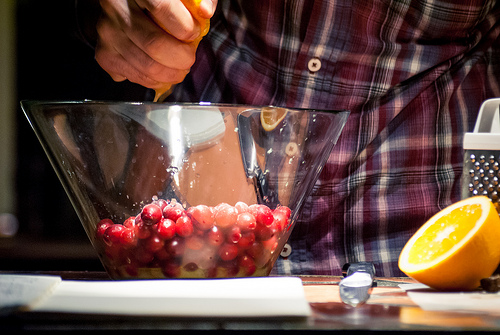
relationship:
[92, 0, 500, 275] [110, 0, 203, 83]
man squeezing orange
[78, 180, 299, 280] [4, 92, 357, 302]
grapes in bowl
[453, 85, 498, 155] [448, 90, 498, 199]
handle on grater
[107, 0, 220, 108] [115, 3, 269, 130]
hand squeezing fruit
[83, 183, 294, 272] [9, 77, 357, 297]
berries in bowl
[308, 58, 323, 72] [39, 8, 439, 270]
button on shirt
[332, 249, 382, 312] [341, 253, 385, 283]
knife has handle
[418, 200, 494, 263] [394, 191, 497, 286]
skin on exterior of fruit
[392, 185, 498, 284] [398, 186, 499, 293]
half of an orange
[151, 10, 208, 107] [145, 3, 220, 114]
cut half of an orange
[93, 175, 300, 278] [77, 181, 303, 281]
bunch of cherries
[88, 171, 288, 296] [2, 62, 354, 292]
cherries inside bowl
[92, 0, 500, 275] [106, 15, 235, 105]
man squeezing an orange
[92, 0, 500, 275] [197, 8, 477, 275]
man wearing shirt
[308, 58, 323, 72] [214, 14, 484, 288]
button on shirt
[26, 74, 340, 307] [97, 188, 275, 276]
bowl of berries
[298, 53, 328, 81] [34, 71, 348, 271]
button above a bowl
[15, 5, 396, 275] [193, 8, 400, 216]
man in shirt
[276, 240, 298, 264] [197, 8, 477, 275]
button on a shirt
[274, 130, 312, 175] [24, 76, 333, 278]
button through a bowl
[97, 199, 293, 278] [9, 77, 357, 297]
berries inside a bowl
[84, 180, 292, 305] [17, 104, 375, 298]
cranberries in bowl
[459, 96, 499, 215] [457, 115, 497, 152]
food grater with handle